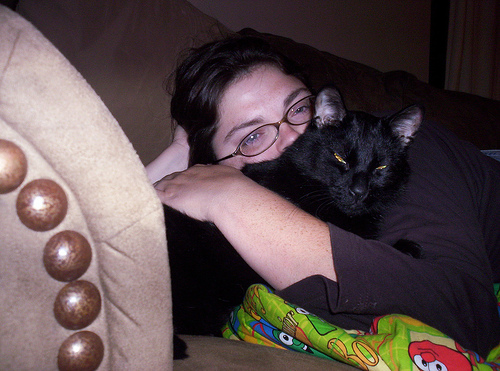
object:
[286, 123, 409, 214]
face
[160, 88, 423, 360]
cat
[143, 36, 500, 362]
woman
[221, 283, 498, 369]
blanket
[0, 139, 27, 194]
rivet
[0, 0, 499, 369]
couch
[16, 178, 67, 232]
rivet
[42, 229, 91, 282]
rivet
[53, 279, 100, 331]
rivet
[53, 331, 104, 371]
rivet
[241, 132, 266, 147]
right-eye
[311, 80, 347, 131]
right-ear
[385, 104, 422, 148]
left-ear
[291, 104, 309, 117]
left-eye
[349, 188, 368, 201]
nose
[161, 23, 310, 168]
hair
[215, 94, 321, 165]
glasses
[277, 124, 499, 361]
shirt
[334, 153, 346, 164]
eye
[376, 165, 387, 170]
eye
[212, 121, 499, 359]
arm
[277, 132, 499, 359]
sleeve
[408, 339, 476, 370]
character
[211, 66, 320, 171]
face